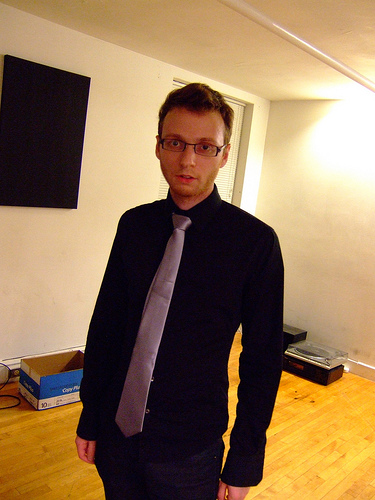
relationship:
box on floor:
[18, 348, 90, 410] [0, 329, 373, 497]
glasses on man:
[154, 133, 229, 158] [75, 81, 283, 494]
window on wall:
[169, 80, 247, 208] [250, 79, 374, 247]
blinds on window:
[174, 83, 244, 206] [169, 80, 253, 202]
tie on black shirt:
[113, 209, 192, 440] [74, 190, 284, 485]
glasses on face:
[152, 128, 230, 159] [157, 105, 225, 197]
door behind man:
[231, 100, 262, 204] [75, 81, 283, 494]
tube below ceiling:
[218, 0, 373, 90] [14, 0, 371, 103]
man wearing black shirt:
[75, 81, 283, 494] [74, 190, 284, 485]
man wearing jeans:
[75, 81, 283, 494] [95, 437, 225, 498]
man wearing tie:
[75, 81, 283, 494] [113, 209, 192, 440]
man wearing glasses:
[75, 81, 283, 494] [154, 134, 227, 162]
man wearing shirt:
[75, 81, 283, 494] [71, 183, 285, 459]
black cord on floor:
[1, 358, 27, 418] [0, 329, 373, 497]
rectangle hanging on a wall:
[6, 53, 86, 220] [3, 3, 267, 401]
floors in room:
[15, 326, 365, 497] [0, 3, 372, 496]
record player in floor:
[280, 336, 346, 385] [0, 329, 373, 497]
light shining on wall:
[318, 108, 369, 174] [313, 113, 341, 144]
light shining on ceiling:
[318, 108, 369, 174] [14, 0, 371, 103]